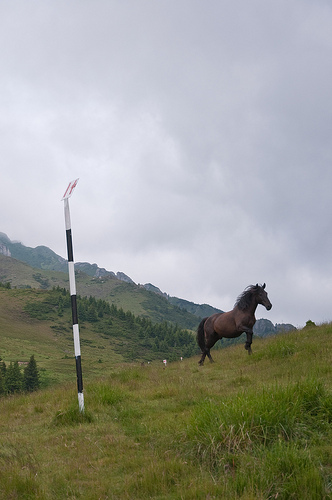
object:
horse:
[196, 282, 273, 366]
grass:
[5, 324, 332, 499]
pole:
[64, 198, 85, 413]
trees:
[55, 286, 198, 358]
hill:
[0, 231, 177, 372]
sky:
[0, 1, 330, 325]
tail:
[196, 317, 208, 357]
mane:
[236, 284, 257, 311]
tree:
[23, 354, 41, 396]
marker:
[61, 177, 80, 200]